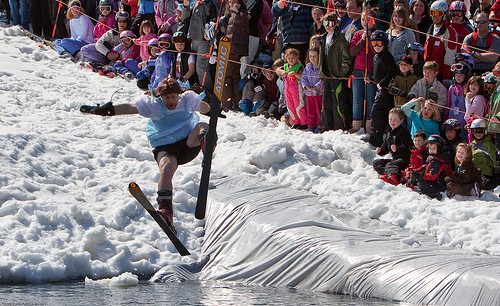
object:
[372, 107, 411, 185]
child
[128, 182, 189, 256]
ski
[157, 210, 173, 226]
foot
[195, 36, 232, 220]
ski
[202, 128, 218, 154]
foot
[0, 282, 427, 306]
water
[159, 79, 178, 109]
head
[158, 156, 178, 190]
leg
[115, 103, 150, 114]
arm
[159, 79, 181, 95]
wig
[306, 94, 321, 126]
pants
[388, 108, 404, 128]
head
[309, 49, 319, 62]
head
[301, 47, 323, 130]
girl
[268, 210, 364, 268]
snow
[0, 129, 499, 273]
ground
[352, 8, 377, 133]
person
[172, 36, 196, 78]
person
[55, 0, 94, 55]
person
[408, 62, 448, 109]
person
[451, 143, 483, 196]
person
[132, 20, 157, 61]
person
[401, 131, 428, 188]
person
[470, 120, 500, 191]
person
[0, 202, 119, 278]
air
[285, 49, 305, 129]
children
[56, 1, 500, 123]
fence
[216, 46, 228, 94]
atomic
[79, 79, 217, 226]
man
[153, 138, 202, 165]
shorts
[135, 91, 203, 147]
dress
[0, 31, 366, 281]
slope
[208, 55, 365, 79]
rope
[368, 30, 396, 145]
kid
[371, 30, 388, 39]
helmet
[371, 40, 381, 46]
goggles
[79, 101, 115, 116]
glove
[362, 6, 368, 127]
pole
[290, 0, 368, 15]
ropes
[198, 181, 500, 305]
sheeting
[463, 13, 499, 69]
man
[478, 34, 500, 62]
arms